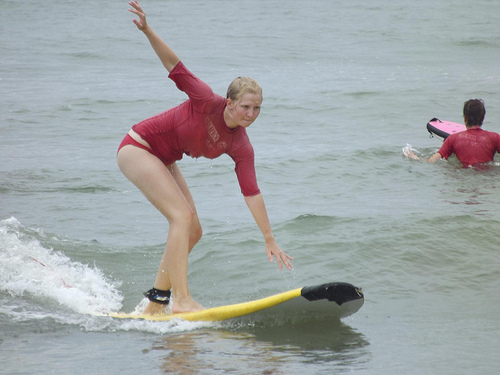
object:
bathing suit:
[132, 60, 262, 197]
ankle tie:
[141, 284, 169, 304]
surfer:
[402, 98, 500, 172]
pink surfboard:
[425, 117, 467, 140]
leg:
[113, 143, 208, 314]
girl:
[116, 0, 296, 312]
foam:
[0, 215, 213, 330]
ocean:
[0, 0, 499, 374]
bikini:
[117, 133, 165, 165]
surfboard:
[425, 117, 483, 139]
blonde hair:
[224, 76, 266, 112]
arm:
[226, 143, 277, 240]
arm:
[143, 29, 217, 101]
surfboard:
[92, 280, 364, 322]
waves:
[0, 211, 126, 328]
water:
[0, 0, 500, 375]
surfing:
[0, 215, 370, 333]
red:
[114, 60, 260, 196]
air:
[0, 0, 499, 82]